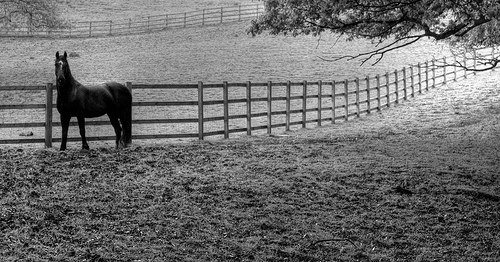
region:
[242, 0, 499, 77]
a tree over the ground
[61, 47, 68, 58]
the ear of a horse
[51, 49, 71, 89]
the head of a horse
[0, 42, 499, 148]
a long wooden fence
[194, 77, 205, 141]
a wooden fence post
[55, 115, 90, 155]
the front legs of a horse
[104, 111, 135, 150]
the hind legs of a horse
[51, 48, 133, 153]
a horse in front of the fence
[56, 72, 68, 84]
the nose of the horse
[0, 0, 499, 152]
a field surrounded by a fence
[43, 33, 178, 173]
a horse looking at the camera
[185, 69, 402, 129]
wooden fence enclosing a pasture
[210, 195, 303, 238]
grass growing in the pasture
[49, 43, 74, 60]
ears on a head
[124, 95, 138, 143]
a long silky tail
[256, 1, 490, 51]
a tree hanging over the pasture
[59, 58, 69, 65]
a white patch of hair on a head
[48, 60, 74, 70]
eyes on a head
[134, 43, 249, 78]
an open field next to the pasture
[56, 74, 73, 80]
nostrils on a nose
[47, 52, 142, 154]
a horse in a meadow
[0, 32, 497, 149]
a fence is behind the horse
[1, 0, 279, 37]
a fence is behind the fence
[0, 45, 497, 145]
the fence is long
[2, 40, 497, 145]
the fence is wooden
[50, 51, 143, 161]
the horse is in front of the fence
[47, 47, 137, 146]
the horse is dark colored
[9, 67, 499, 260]
the field is very bare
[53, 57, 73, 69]
horse has spot on nose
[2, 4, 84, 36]
a tree is in the background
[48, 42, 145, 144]
horse standing in field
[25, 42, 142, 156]
horse with white spot on head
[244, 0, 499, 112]
tree hanging in corner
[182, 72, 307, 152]
fence forming squares in shape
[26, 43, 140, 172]
horse facing the camera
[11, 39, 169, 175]
horse with four legs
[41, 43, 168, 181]
horse with ears pointing up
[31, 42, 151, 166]
horse with all legs on ground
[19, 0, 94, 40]
tree in background by fence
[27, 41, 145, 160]
muscular horse near fence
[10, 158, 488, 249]
Field of grass the horse is standing in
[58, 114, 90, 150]
Horse's front legs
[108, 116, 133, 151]
Horse's back legs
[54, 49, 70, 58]
Horse's ears pointing upwards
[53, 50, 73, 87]
Horse's entire head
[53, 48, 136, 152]
Entire horse standing in the field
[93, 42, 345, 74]
Next field behind the horse beyond the fence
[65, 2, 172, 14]
Farthest field beyond the last fence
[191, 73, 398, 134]
Fence in the foreground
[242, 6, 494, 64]
Closest tree to us in the foreground